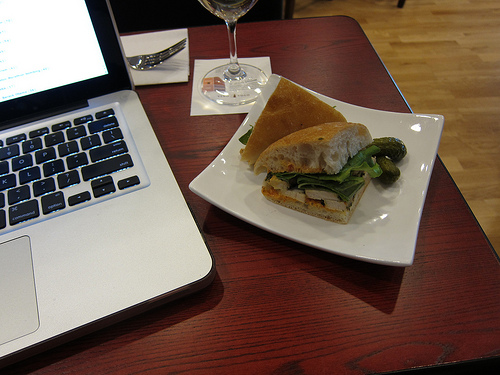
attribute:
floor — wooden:
[182, 139, 479, 271]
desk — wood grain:
[7, 11, 499, 372]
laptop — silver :
[1, 1, 216, 373]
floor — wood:
[361, 19, 496, 143]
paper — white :
[190, 56, 274, 115]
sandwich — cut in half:
[236, 89, 421, 231]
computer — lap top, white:
[4, 9, 234, 357]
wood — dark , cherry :
[150, 19, 497, 374]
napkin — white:
[152, 42, 174, 72]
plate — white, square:
[186, 67, 448, 277]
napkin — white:
[190, 57, 353, 213]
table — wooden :
[2, 91, 497, 375]